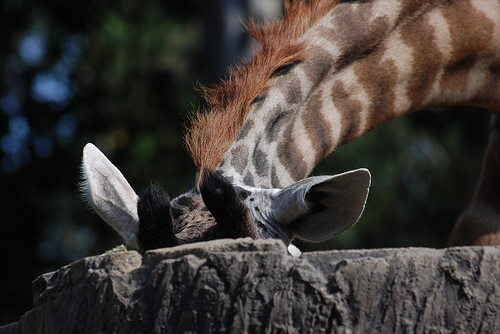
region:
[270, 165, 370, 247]
the ear of the giraffe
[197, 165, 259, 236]
the horn on the giraffe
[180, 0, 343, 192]
the mane on the giraffe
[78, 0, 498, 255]
the giraffe with its head down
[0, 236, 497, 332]
the wood piece near the giraffe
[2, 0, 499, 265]
the blurry area behind the giraffe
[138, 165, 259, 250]
the dark hairs on the horns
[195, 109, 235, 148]
brown hair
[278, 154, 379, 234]
left ear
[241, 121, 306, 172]
the neck of the animal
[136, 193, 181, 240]
hair on the horns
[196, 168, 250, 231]
horns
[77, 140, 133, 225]
hair on the ear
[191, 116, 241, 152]
brown hair on the animal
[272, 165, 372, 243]
gray left ear of a giraffe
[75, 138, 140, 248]
right gray ear of a giraffe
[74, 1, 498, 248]
brown and white giraffe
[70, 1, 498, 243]
giraffe hiding head behind rock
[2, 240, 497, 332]
dark gray stone mass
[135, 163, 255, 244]
two pointed giraffe horns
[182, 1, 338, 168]
short brown mane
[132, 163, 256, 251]
two black giraffe horns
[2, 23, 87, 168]
blurry blue sky showing through trees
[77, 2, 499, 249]
giraffe bending its neck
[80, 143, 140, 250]
A giraffes right ear.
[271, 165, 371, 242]
A giraffes left ear.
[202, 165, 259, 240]
A black and brown giraffe horn.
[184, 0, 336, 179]
Brown giraffe mane.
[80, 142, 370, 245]
Grey left and right ears of a giraffe.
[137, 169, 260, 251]
Black and brown horns of a giraffe.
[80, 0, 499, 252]
A brown and white giraffe with grey ears and black horns.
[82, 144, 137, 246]
A hairy grey right giraffe ear.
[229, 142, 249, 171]
brown spot on giraffe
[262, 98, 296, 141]
brown spot on giraffe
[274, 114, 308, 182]
brown spot on giraffe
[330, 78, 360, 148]
brown spot on giraffe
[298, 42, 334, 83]
brown spot on giraffe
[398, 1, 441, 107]
brown spot on giraffe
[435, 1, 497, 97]
brown spot on giraffe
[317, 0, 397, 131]
brown spot on giraffe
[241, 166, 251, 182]
brown spot on giraffe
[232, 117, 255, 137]
brown spot on giraffe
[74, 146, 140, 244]
The left ear of the giraffe.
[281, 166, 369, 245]
The right ear of the giraffe.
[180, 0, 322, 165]
The mane of the giraffe.